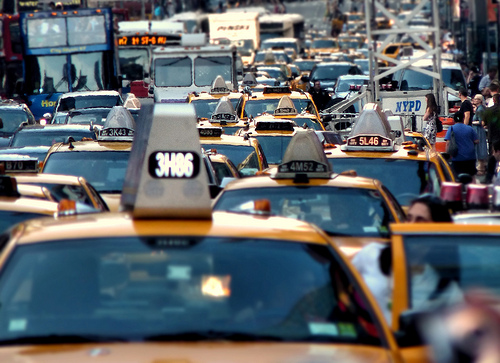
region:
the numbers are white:
[146, 141, 204, 177]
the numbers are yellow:
[345, 125, 390, 153]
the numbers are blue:
[271, 149, 336, 181]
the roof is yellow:
[26, 209, 333, 265]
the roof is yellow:
[246, 164, 386, 199]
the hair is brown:
[411, 189, 451, 244]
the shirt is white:
[354, 230, 441, 319]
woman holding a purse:
[445, 108, 482, 176]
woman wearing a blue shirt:
[445, 110, 482, 180]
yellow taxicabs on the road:
[0, 71, 458, 361]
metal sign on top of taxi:
[119, 100, 212, 221]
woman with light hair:
[470, 90, 490, 177]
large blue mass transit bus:
[20, 4, 122, 124]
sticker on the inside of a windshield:
[304, 315, 358, 340]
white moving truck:
[204, 7, 266, 59]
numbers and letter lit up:
[151, 148, 196, 180]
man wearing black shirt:
[450, 85, 475, 129]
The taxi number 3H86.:
[151, 152, 194, 177]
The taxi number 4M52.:
[276, 162, 326, 179]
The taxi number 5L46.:
[344, 132, 391, 148]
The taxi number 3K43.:
[101, 127, 134, 137]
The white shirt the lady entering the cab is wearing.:
[356, 247, 458, 324]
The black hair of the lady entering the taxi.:
[383, 192, 456, 297]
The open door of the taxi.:
[390, 219, 498, 351]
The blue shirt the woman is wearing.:
[447, 123, 473, 162]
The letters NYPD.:
[392, 100, 423, 112]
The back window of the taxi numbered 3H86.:
[5, 239, 380, 348]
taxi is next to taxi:
[0, 211, 496, 361]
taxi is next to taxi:
[214, 129, 411, 262]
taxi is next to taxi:
[2, 175, 68, 235]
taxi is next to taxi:
[2, 155, 110, 213]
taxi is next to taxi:
[37, 104, 135, 213]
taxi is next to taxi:
[197, 120, 269, 178]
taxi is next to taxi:
[271, 95, 323, 131]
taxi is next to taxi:
[321, 102, 457, 219]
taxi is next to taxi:
[186, 73, 248, 122]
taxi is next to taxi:
[120, 90, 143, 122]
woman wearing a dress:
[412, 89, 444, 149]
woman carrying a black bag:
[415, 87, 441, 144]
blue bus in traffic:
[20, 3, 122, 96]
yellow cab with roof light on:
[338, 96, 439, 201]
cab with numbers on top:
[30, 90, 387, 360]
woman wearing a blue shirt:
[446, 104, 478, 172]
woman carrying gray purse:
[442, 104, 482, 175]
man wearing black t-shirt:
[450, 88, 475, 125]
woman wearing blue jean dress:
[471, 90, 488, 159]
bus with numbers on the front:
[110, 20, 175, 101]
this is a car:
[12, 177, 347, 362]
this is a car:
[386, 201, 498, 341]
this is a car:
[206, 164, 422, 293]